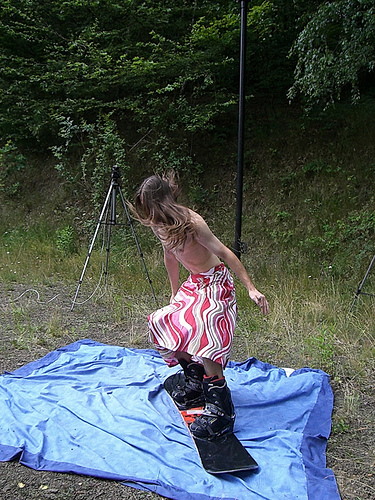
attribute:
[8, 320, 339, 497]
blanket — blue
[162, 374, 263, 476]
snowboard — black, red